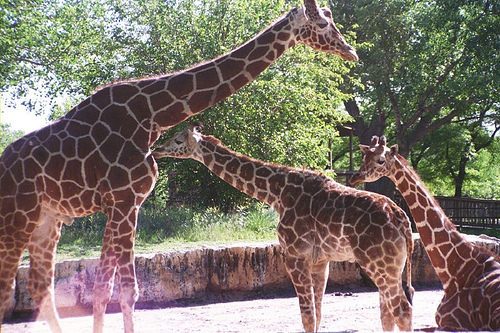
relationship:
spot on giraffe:
[74, 131, 97, 158] [5, 1, 370, 318]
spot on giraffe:
[114, 140, 148, 171] [5, 1, 370, 318]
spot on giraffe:
[253, 164, 273, 180] [148, 123, 419, 331]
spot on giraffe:
[251, 175, 270, 192] [148, 123, 419, 331]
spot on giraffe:
[256, 189, 268, 201] [148, 123, 419, 331]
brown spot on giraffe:
[436, 230, 460, 242] [349, 125, 496, 320]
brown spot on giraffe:
[446, 250, 465, 278] [349, 125, 496, 320]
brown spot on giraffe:
[305, 186, 323, 224] [157, 132, 425, 324]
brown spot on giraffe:
[218, 59, 248, 81] [0, 22, 366, 294]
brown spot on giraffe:
[106, 162, 131, 192] [0, 22, 366, 294]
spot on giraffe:
[415, 223, 432, 248] [351, 138, 498, 329]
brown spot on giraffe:
[270, 175, 278, 191] [29, 15, 463, 309]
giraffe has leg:
[5, 1, 370, 318] [112, 200, 141, 331]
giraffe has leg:
[5, 1, 370, 318] [90, 214, 121, 332]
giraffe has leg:
[5, 1, 370, 318] [25, 216, 66, 330]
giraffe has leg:
[5, 1, 370, 318] [0, 201, 40, 307]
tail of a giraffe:
[397, 207, 415, 307] [148, 123, 419, 331]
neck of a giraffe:
[394, 153, 458, 273] [351, 138, 498, 329]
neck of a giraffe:
[212, 127, 299, 204] [148, 123, 419, 331]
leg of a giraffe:
[378, 294, 393, 331] [148, 123, 419, 331]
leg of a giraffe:
[385, 284, 413, 331] [148, 123, 419, 331]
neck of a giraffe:
[212, 127, 299, 204] [5, 1, 370, 318]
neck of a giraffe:
[212, 127, 299, 204] [357, 130, 494, 325]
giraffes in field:
[149, 118, 415, 331] [2, 283, 452, 331]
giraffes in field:
[351, 132, 499, 329] [2, 283, 452, 331]